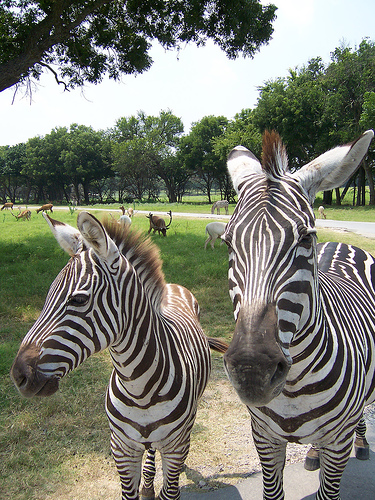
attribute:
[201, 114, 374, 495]
zebra — adult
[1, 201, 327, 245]
animals —  Other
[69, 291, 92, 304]
eye — young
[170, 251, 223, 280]
grass —  tall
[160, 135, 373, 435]
zebra. —  small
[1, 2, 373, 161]
sky —  cloudy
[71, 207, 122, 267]
ear —   young zebra's, the  left 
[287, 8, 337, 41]
sky —  bright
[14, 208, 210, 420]
zebra — the  right ,   young zebra's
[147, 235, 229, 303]
grass —  green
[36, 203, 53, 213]
animal —  Three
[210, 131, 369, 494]
zebra — adult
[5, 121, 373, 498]
zebras —  Two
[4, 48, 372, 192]
trees —  green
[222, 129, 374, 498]
zebra —  black and white, adult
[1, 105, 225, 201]
trees —   leafy ,  green, in Large grove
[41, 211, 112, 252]
ears —  Two ,   zebra's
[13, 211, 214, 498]
zebra —   young ,  black and white,  smaller,   the left ,  small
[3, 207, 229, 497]
grass — green